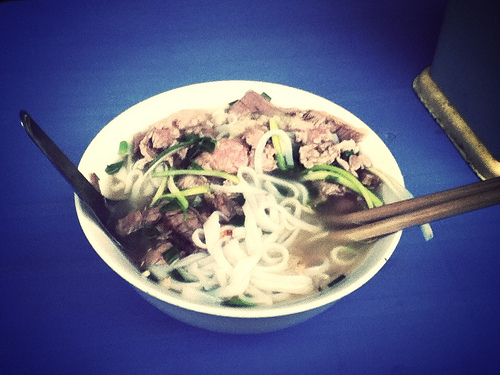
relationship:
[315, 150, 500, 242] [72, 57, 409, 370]
chopsticks near bowl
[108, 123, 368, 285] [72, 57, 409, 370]
noodles in bowl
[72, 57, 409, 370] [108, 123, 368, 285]
bowl of noodles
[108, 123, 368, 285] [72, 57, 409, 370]
noodles hanging off bowl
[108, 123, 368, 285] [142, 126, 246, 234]
noodles have meat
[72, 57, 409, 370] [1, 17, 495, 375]
bowl on table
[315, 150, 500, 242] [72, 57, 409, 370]
chopsticks in bowl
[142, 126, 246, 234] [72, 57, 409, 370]
meat in bowl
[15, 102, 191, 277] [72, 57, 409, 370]
spoon in bowl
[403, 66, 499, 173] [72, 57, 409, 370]
object near bowl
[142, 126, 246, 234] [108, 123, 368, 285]
meat on noodles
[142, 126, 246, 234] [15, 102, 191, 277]
meat on spoon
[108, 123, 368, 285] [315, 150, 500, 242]
noodles by chopsticks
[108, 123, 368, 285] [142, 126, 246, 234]
noodles near meat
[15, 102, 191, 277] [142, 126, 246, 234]
spoon under meat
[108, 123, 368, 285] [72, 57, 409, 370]
noodles hanging out bowl